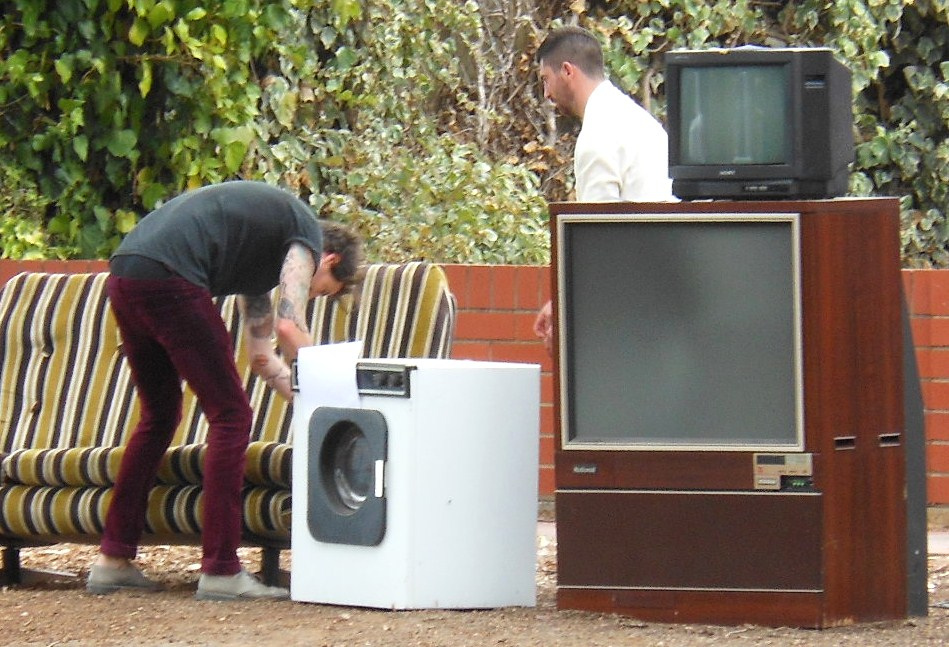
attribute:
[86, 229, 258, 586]
pants — red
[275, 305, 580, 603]
machine — white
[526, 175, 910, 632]
television — wooden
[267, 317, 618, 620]
dryer — small, white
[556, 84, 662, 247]
shirt — white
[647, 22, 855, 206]
tv — old, black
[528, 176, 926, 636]
tv — old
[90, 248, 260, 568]
pants — red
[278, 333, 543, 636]
washing machine — gray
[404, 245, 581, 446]
wall — small, red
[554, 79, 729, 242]
top — white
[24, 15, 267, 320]
leaves — green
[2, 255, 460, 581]
couch — striped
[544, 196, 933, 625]
television — large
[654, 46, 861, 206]
tv — small, black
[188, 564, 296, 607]
shoe — gray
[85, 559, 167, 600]
shoe — gray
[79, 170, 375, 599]
man — bent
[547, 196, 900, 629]
tv — old style, big screen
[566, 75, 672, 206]
shirt — white, dress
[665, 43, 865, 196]
tv — small, boxy